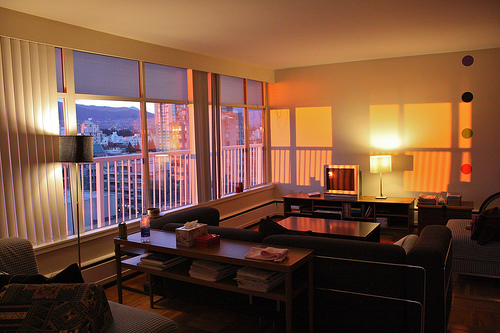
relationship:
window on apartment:
[55, 48, 196, 234] [1, 3, 500, 332]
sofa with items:
[0, 239, 173, 327] [1, 264, 110, 332]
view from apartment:
[56, 48, 266, 236] [1, 3, 500, 332]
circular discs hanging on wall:
[461, 53, 476, 176] [267, 49, 499, 206]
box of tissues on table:
[174, 217, 208, 245] [114, 227, 312, 326]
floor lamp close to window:
[57, 134, 97, 281] [55, 48, 196, 234]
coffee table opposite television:
[275, 211, 381, 240] [321, 163, 358, 196]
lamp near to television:
[369, 154, 392, 198] [321, 163, 358, 196]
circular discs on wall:
[461, 53, 476, 176] [267, 49, 499, 206]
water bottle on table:
[139, 212, 150, 240] [114, 227, 312, 326]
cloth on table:
[247, 246, 291, 260] [114, 227, 312, 326]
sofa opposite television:
[147, 204, 453, 332] [321, 163, 358, 196]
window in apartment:
[55, 48, 196, 234] [1, 3, 500, 332]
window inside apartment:
[213, 74, 273, 198] [1, 3, 500, 332]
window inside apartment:
[55, 48, 196, 234] [1, 3, 500, 332]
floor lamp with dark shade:
[57, 134, 97, 281] [60, 135, 94, 161]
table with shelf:
[114, 227, 312, 326] [117, 239, 285, 299]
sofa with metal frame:
[147, 204, 453, 332] [318, 258, 427, 326]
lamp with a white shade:
[369, 154, 392, 198] [369, 153, 391, 175]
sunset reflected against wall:
[269, 101, 474, 203] [267, 49, 499, 206]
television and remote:
[321, 163, 358, 196] [305, 188, 318, 196]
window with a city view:
[55, 48, 196, 234] [56, 48, 266, 236]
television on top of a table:
[321, 163, 358, 196] [283, 194, 414, 233]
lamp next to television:
[369, 154, 392, 198] [321, 163, 358, 196]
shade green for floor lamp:
[60, 135, 94, 161] [57, 134, 97, 281]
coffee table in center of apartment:
[275, 211, 381, 240] [1, 3, 500, 332]